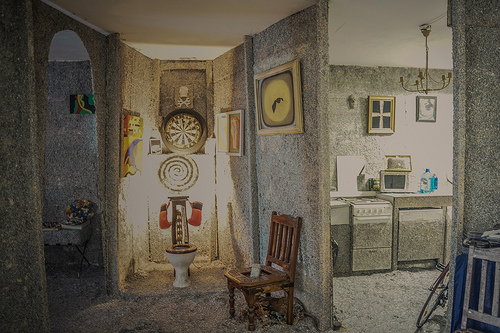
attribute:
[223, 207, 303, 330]
chair — wooden